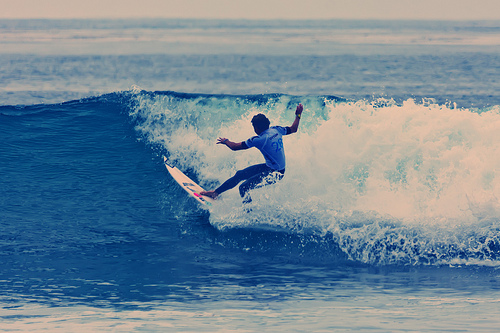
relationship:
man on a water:
[197, 105, 303, 216] [2, 19, 499, 331]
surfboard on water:
[161, 153, 214, 207] [2, 19, 499, 331]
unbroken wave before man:
[1, 85, 139, 250] [197, 105, 303, 216]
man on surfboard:
[197, 105, 303, 216] [161, 153, 214, 207]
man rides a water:
[197, 105, 303, 216] [2, 19, 499, 331]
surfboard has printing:
[161, 153, 214, 207] [180, 182, 200, 196]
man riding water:
[197, 105, 303, 216] [2, 19, 499, 331]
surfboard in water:
[161, 153, 214, 207] [2, 19, 499, 331]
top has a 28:
[243, 125, 290, 171] [268, 139, 286, 156]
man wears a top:
[197, 105, 303, 216] [243, 125, 290, 171]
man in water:
[197, 105, 303, 216] [2, 19, 499, 331]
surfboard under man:
[161, 153, 214, 207] [197, 105, 303, 216]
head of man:
[251, 114, 272, 132] [197, 105, 303, 216]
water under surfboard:
[2, 19, 499, 331] [161, 153, 214, 207]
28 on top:
[268, 139, 286, 156] [243, 125, 290, 171]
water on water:
[2, 19, 499, 331] [2, 19, 499, 331]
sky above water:
[3, 0, 498, 24] [2, 19, 499, 331]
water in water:
[2, 19, 499, 331] [2, 19, 499, 331]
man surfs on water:
[197, 105, 303, 216] [2, 19, 499, 331]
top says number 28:
[243, 125, 290, 171] [268, 139, 286, 156]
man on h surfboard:
[197, 105, 303, 216] [161, 153, 214, 207]